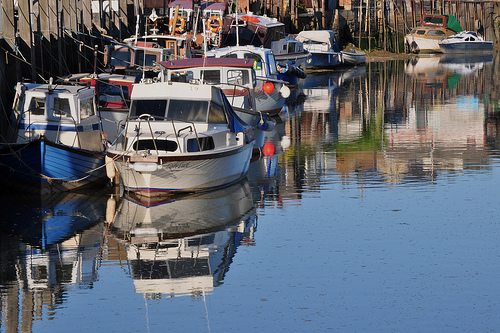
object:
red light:
[253, 79, 279, 95]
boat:
[205, 43, 294, 117]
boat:
[153, 56, 266, 131]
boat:
[91, 33, 166, 98]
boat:
[133, 9, 215, 74]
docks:
[0, 3, 367, 245]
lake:
[6, 192, 499, 332]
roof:
[155, 53, 257, 74]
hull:
[7, 138, 107, 188]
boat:
[2, 81, 105, 188]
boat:
[268, 35, 309, 71]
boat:
[293, 27, 336, 68]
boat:
[330, 48, 370, 69]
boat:
[403, 14, 455, 52]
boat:
[434, 25, 498, 51]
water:
[12, 55, 497, 327]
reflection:
[104, 154, 280, 299]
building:
[373, 78, 497, 187]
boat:
[72, 70, 137, 150]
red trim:
[77, 76, 133, 113]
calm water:
[0, 57, 499, 331]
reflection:
[34, 198, 101, 253]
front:
[108, 141, 227, 199]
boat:
[105, 80, 258, 196]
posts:
[2, 4, 129, 64]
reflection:
[288, 69, 490, 191]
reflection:
[432, 103, 488, 146]